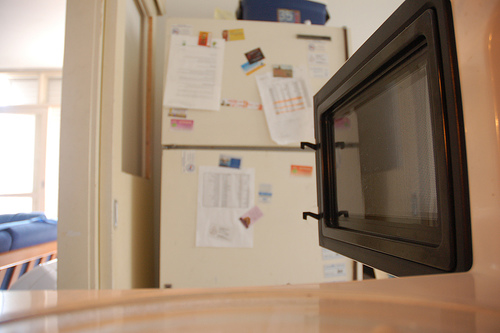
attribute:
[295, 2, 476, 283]
door — microwave, black, opened, open, glass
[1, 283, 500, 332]
dish — glass, round, microwave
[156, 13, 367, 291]
fridge — beige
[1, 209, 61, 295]
couch — blue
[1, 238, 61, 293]
frame — wood, wooden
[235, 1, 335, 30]
tub — blue, plastic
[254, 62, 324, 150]
paper — highlighted, white, highlights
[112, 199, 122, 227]
switch — light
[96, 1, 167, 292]
wall — beige, sliding